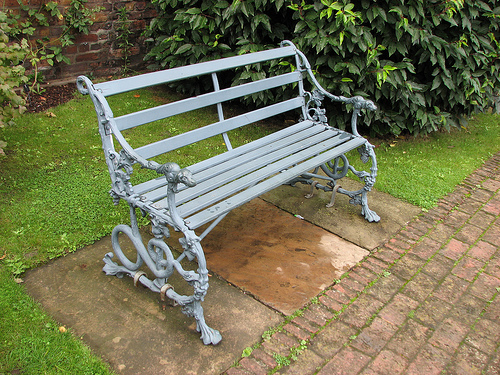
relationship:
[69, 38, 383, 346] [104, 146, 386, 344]
bench has legs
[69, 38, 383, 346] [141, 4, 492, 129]
bench touches bush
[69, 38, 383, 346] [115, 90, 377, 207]
bench has arms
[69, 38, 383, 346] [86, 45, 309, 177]
bench has back